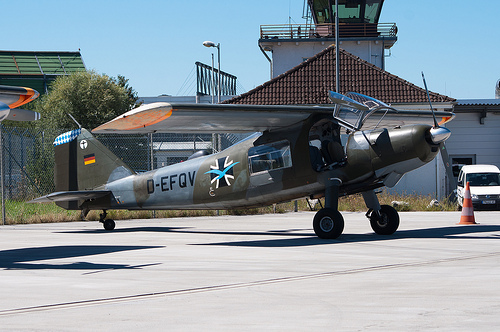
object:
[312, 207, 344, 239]
tire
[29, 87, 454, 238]
plane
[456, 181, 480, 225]
cone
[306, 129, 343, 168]
door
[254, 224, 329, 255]
shadow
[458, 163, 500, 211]
car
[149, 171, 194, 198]
letters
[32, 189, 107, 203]
wing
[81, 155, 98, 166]
flag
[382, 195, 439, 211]
grass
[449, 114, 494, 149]
side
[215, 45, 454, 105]
roof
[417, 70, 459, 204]
propeller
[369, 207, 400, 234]
tire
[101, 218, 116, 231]
tire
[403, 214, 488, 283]
concrete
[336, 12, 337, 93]
post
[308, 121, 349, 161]
cockpit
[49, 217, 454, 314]
ground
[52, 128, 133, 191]
tail